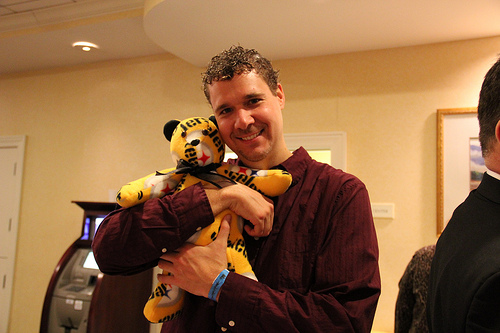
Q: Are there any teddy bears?
A: Yes, there is a teddy bear.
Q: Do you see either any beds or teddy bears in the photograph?
A: Yes, there is a teddy bear.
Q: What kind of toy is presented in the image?
A: The toy is a teddy bear.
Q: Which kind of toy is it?
A: The toy is a teddy bear.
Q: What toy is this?
A: This is a teddy bear.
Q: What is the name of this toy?
A: This is a teddy bear.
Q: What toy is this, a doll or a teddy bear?
A: This is a teddy bear.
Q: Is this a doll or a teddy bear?
A: This is a teddy bear.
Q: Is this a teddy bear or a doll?
A: This is a teddy bear.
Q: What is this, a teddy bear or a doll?
A: This is a teddy bear.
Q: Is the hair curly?
A: Yes, the hair is curly.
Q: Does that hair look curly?
A: Yes, the hair is curly.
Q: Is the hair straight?
A: No, the hair is curly.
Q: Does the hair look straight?
A: No, the hair is curly.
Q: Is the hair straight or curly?
A: The hair is curly.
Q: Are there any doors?
A: Yes, there is a door.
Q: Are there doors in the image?
A: Yes, there is a door.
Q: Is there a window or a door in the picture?
A: Yes, there is a door.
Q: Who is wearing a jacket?
A: The man is wearing a jacket.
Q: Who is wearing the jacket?
A: The man is wearing a jacket.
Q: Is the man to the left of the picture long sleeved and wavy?
A: Yes, the man is long sleeved and wavy.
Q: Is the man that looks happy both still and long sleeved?
A: No, the man is long sleeved but wavy.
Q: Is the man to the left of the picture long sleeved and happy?
A: Yes, the man is long sleeved and happy.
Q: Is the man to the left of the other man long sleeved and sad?
A: No, the man is long sleeved but happy.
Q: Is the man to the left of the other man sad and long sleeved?
A: No, the man is long sleeved but happy.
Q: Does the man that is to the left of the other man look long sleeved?
A: Yes, the man is long sleeved.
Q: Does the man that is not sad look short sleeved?
A: No, the man is long sleeved.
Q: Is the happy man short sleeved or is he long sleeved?
A: The man is long sleeved.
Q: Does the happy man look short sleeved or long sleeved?
A: The man is long sleeved.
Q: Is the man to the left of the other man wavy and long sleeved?
A: Yes, the man is wavy and long sleeved.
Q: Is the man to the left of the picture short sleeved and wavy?
A: No, the man is wavy but long sleeved.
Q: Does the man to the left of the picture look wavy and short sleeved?
A: No, the man is wavy but long sleeved.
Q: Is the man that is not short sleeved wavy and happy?
A: Yes, the man is wavy and happy.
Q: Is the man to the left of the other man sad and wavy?
A: No, the man is wavy but happy.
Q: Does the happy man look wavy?
A: Yes, the man is wavy.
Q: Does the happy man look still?
A: No, the man is wavy.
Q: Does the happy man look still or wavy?
A: The man is wavy.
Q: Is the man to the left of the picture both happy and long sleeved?
A: Yes, the man is happy and long sleeved.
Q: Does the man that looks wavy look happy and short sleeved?
A: No, the man is happy but long sleeved.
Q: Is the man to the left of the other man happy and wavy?
A: Yes, the man is happy and wavy.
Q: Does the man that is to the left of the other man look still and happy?
A: No, the man is happy but wavy.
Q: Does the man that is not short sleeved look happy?
A: Yes, the man is happy.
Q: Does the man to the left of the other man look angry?
A: No, the man is happy.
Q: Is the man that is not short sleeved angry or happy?
A: The man is happy.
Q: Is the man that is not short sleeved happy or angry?
A: The man is happy.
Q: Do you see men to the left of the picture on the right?
A: Yes, there is a man to the left of the picture.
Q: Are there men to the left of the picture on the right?
A: Yes, there is a man to the left of the picture.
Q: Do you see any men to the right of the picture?
A: No, the man is to the left of the picture.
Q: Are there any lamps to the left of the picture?
A: No, there is a man to the left of the picture.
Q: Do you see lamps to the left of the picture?
A: No, there is a man to the left of the picture.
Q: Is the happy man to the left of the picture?
A: Yes, the man is to the left of the picture.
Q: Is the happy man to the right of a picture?
A: No, the man is to the left of a picture.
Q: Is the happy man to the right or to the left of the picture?
A: The man is to the left of the picture.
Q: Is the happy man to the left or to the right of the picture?
A: The man is to the left of the picture.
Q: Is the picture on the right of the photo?
A: Yes, the picture is on the right of the image.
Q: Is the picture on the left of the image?
A: No, the picture is on the right of the image.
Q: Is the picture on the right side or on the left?
A: The picture is on the right of the image.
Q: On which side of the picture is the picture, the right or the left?
A: The picture is on the right of the image.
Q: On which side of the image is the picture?
A: The picture is on the right of the image.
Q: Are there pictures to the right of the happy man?
A: Yes, there is a picture to the right of the man.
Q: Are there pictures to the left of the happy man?
A: No, the picture is to the right of the man.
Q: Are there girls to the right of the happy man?
A: No, there is a picture to the right of the man.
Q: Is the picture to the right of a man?
A: Yes, the picture is to the right of a man.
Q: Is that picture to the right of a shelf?
A: No, the picture is to the right of a man.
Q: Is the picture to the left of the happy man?
A: No, the picture is to the right of the man.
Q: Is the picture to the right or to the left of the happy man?
A: The picture is to the right of the man.